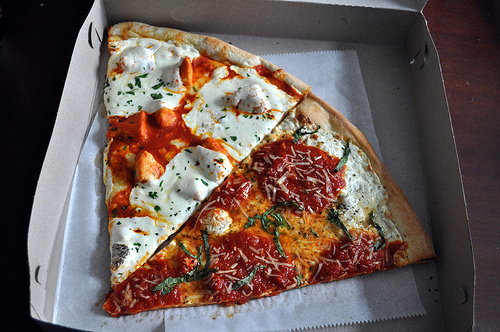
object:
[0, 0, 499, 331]
table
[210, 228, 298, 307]
pepperoni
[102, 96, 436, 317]
slice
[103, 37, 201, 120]
cheese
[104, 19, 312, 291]
slice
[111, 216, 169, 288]
cheese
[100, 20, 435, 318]
pizza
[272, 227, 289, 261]
parsley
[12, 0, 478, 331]
box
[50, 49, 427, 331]
paper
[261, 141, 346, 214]
sauce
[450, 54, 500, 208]
surface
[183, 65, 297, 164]
cheese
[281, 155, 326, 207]
sauce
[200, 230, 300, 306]
ingredient